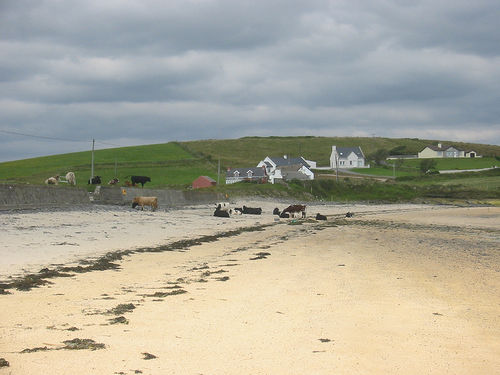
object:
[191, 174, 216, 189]
red house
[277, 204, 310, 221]
cows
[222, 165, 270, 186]
house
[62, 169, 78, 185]
cow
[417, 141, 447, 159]
house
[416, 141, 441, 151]
roof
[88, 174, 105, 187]
cow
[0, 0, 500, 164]
sky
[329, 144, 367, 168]
house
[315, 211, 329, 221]
cows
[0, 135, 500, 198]
field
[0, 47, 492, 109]
cloud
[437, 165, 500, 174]
street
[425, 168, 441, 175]
car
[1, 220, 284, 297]
bunch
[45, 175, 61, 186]
cow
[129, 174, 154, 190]
cow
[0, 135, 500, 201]
hill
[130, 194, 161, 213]
cow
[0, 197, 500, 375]
beach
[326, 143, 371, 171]
farm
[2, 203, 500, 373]
sand